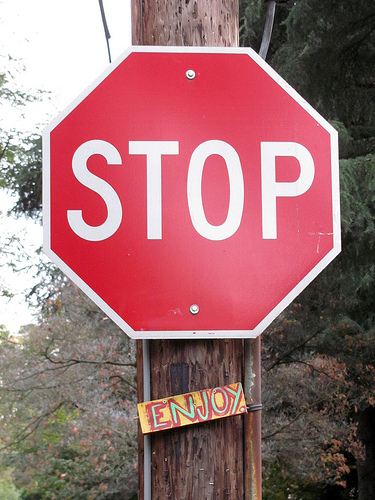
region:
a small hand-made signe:
[123, 379, 258, 444]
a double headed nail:
[184, 298, 201, 319]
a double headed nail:
[175, 64, 198, 91]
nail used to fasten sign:
[183, 299, 202, 317]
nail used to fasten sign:
[178, 64, 199, 88]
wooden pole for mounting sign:
[152, 340, 239, 394]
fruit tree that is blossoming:
[0, 261, 139, 488]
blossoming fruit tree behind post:
[258, 269, 371, 482]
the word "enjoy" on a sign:
[132, 376, 253, 442]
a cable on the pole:
[128, 336, 155, 498]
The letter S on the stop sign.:
[68, 135, 131, 245]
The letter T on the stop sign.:
[125, 132, 182, 247]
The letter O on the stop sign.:
[189, 136, 249, 245]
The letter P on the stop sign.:
[259, 136, 313, 242]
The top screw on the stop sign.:
[183, 68, 200, 85]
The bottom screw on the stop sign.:
[182, 301, 206, 317]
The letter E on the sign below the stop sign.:
[146, 403, 169, 423]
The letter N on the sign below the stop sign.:
[163, 397, 197, 423]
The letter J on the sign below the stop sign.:
[193, 390, 214, 420]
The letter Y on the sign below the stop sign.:
[223, 377, 244, 413]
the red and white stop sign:
[31, 38, 362, 362]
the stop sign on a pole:
[41, 43, 342, 361]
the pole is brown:
[120, 0, 270, 480]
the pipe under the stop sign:
[240, 336, 272, 489]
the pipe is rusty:
[246, 336, 264, 494]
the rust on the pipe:
[252, 420, 260, 444]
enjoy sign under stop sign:
[129, 379, 253, 439]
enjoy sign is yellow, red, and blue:
[135, 372, 251, 436]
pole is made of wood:
[118, 2, 275, 478]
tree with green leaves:
[274, 15, 373, 343]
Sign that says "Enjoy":
[127, 385, 243, 418]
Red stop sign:
[40, 76, 334, 322]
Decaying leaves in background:
[312, 343, 366, 492]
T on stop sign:
[126, 136, 183, 245]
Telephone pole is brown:
[127, 348, 268, 498]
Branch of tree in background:
[38, 341, 123, 378]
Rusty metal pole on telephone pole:
[246, 349, 269, 498]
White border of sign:
[41, 125, 53, 260]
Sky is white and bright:
[5, 10, 105, 75]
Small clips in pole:
[176, 454, 237, 489]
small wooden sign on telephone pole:
[131, 374, 255, 449]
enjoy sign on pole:
[128, 379, 266, 440]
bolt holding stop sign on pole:
[183, 301, 203, 318]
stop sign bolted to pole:
[31, 32, 364, 352]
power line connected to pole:
[89, 3, 122, 48]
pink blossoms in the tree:
[39, 424, 113, 475]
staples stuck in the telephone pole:
[166, 453, 244, 487]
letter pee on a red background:
[250, 129, 316, 244]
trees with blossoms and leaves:
[285, 377, 357, 474]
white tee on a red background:
[125, 133, 182, 243]